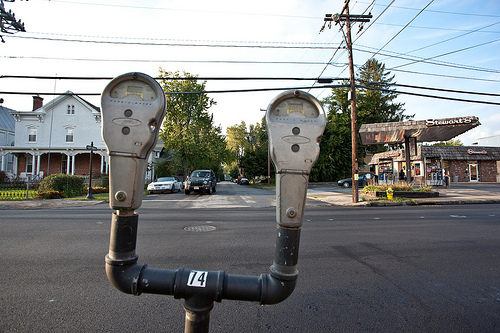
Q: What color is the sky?
A: Blue.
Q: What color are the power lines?
A: Black.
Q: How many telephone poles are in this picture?
A: One.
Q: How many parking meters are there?
A: Two.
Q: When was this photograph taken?
A: Daytime.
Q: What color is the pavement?
A: Grey.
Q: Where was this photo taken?
A: On the street.